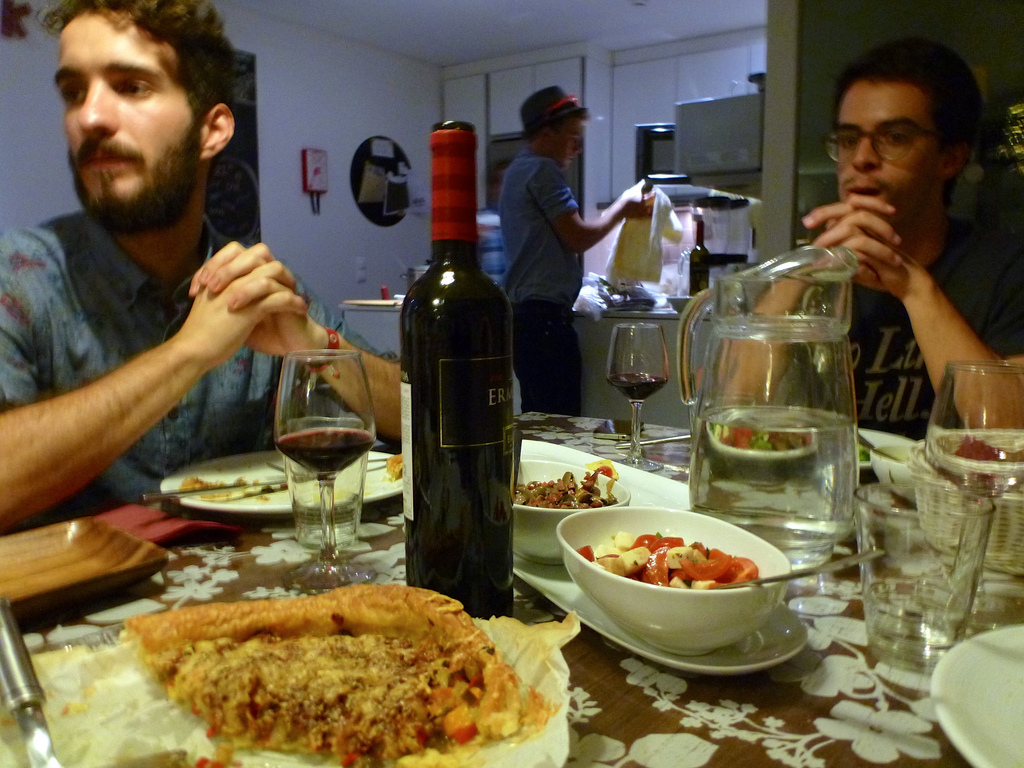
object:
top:
[433, 121, 479, 242]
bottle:
[399, 119, 514, 618]